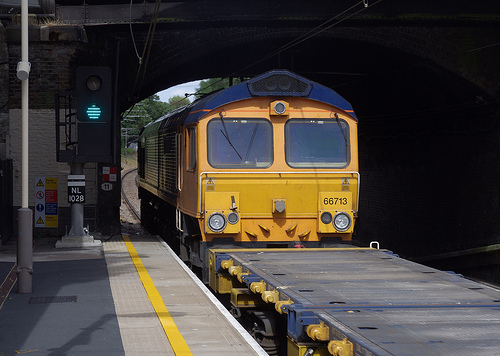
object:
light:
[83, 102, 106, 121]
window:
[280, 116, 353, 173]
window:
[206, 117, 276, 170]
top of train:
[141, 67, 357, 128]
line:
[119, 228, 194, 355]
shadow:
[0, 247, 187, 356]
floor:
[0, 236, 270, 355]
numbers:
[321, 195, 349, 208]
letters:
[66, 184, 87, 205]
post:
[11, 0, 35, 299]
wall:
[0, 27, 122, 237]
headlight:
[208, 212, 228, 234]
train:
[131, 59, 374, 256]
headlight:
[332, 208, 353, 232]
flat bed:
[191, 235, 499, 354]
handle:
[195, 166, 362, 215]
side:
[131, 102, 203, 209]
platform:
[0, 0, 270, 355]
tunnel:
[63, 5, 500, 252]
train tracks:
[115, 161, 153, 238]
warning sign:
[32, 172, 62, 230]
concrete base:
[15, 205, 37, 296]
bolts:
[213, 251, 352, 356]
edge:
[157, 233, 273, 356]